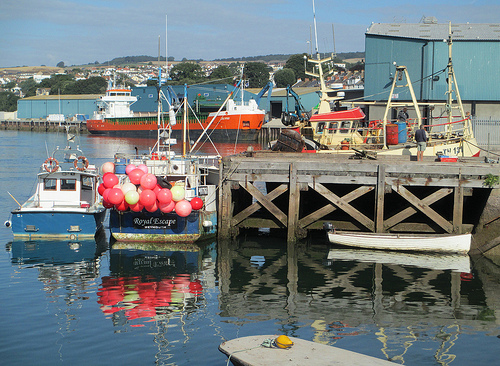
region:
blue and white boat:
[13, 161, 103, 256]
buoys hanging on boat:
[102, 164, 204, 217]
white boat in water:
[326, 224, 476, 254]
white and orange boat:
[88, 83, 265, 143]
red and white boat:
[293, 110, 482, 160]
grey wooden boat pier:
[223, 147, 498, 237]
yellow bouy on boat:
[268, 334, 293, 349]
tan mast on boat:
[446, 23, 455, 136]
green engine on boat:
[323, 220, 334, 236]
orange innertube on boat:
[45, 157, 59, 173]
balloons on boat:
[99, 160, 204, 212]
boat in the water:
[4, 123, 102, 276]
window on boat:
[45, 179, 56, 188]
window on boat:
[60, 177, 79, 189]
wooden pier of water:
[221, 139, 481, 251]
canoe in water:
[325, 222, 474, 254]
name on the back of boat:
[128, 215, 180, 227]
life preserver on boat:
[38, 156, 61, 171]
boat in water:
[96, 74, 261, 141]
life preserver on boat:
[71, 156, 88, 171]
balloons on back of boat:
[94, 172, 206, 217]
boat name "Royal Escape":
[130, 214, 177, 228]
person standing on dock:
[412, 123, 428, 163]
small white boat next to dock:
[323, 226, 473, 253]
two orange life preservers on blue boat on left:
[43, 154, 94, 174]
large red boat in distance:
[80, 111, 266, 135]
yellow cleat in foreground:
[270, 328, 295, 356]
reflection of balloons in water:
[100, 273, 206, 320]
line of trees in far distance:
[32, 51, 299, 68]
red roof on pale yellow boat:
[309, 108, 369, 122]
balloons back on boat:
[80, 163, 212, 228]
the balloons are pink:
[135, 170, 175, 207]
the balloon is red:
[185, 195, 205, 212]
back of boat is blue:
[103, 203, 200, 240]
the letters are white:
[132, 214, 202, 241]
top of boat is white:
[20, 155, 97, 204]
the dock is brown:
[205, 142, 495, 247]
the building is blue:
[344, 28, 496, 113]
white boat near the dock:
[297, 204, 487, 263]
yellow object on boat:
[269, 323, 301, 355]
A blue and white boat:
[8, 157, 103, 244]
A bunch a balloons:
[98, 171, 205, 221]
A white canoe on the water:
[318, 220, 480, 266]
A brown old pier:
[215, 141, 499, 226]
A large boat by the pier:
[273, 46, 488, 166]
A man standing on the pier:
[409, 123, 436, 161]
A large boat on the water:
[85, 78, 273, 142]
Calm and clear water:
[261, 260, 486, 331]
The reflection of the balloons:
[98, 263, 206, 325]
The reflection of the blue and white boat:
[11, 235, 103, 356]